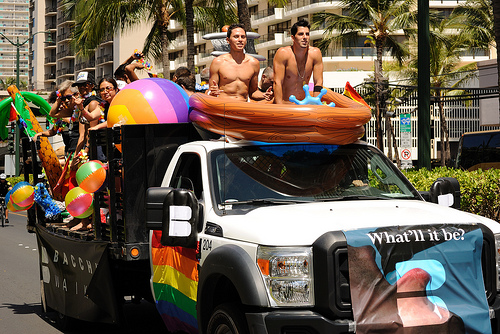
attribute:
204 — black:
[188, 224, 276, 266]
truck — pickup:
[178, 139, 445, 307]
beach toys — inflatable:
[4, 78, 377, 230]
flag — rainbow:
[121, 224, 211, 295]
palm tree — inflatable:
[2, 87, 62, 193]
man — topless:
[207, 18, 269, 101]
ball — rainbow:
[104, 73, 193, 126]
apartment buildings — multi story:
[245, 0, 376, 67]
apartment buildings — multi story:
[1, 0, 153, 110]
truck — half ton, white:
[23, 128, 488, 328]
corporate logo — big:
[341, 224, 495, 332]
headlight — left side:
[255, 247, 316, 305]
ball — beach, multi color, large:
[97, 82, 184, 127]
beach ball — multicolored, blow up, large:
[107, 76, 189, 124]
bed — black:
[26, 198, 146, 274]